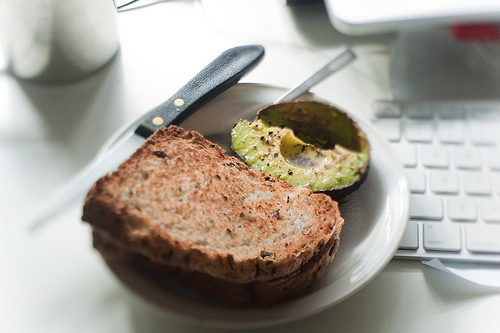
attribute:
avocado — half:
[229, 98, 372, 201]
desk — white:
[1, 2, 498, 332]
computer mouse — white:
[5, 2, 122, 86]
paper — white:
[432, 257, 499, 284]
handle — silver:
[275, 45, 362, 107]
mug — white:
[0, 1, 120, 85]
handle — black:
[130, 41, 265, 138]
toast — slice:
[96, 138, 369, 275]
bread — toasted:
[61, 118, 386, 318]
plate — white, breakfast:
[90, 81, 410, 329]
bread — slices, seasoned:
[84, 120, 344, 280]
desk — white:
[25, 116, 81, 159]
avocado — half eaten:
[230, 118, 370, 195]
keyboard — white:
[362, 90, 498, 265]